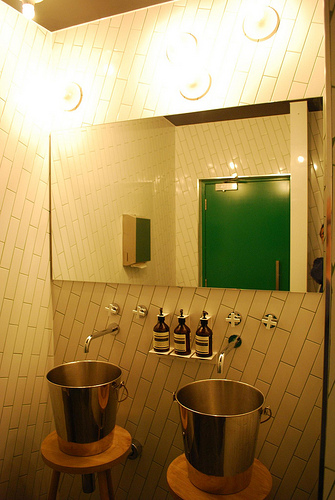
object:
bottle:
[195, 310, 213, 358]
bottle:
[173, 309, 191, 356]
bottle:
[153, 308, 170, 352]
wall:
[137, 344, 175, 474]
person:
[310, 222, 324, 291]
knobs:
[105, 303, 120, 315]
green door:
[200, 179, 290, 292]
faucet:
[217, 335, 242, 375]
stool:
[166, 452, 273, 499]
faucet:
[84, 322, 120, 353]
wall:
[54, 276, 84, 349]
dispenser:
[122, 213, 151, 267]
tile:
[195, 129, 270, 164]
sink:
[42, 318, 132, 456]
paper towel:
[133, 255, 149, 268]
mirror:
[44, 102, 331, 313]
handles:
[223, 312, 275, 329]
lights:
[42, 56, 268, 153]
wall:
[106, 126, 195, 177]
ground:
[227, 70, 249, 84]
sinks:
[172, 376, 270, 488]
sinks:
[43, 360, 120, 458]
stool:
[40, 424, 131, 499]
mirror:
[37, 97, 322, 295]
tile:
[50, 284, 314, 498]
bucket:
[173, 378, 272, 495]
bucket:
[45, 359, 129, 456]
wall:
[281, 1, 323, 78]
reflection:
[304, 225, 330, 281]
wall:
[6, 38, 40, 240]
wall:
[253, 297, 316, 484]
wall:
[19, 292, 42, 454]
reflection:
[302, 219, 320, 284]